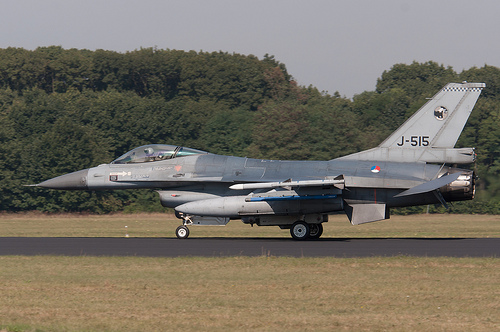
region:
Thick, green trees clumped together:
[0, 48, 498, 213]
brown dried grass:
[3, 212, 498, 329]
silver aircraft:
[22, 79, 484, 236]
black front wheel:
[176, 224, 189, 237]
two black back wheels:
[292, 223, 324, 239]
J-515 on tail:
[396, 134, 431, 149]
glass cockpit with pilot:
[111, 144, 198, 164]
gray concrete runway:
[0, 235, 498, 255]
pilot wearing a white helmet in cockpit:
[140, 145, 152, 157]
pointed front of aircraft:
[22, 167, 89, 189]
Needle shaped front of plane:
[24, 182, 36, 186]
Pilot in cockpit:
[145, 146, 154, 156]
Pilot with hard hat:
[143, 146, 154, 156]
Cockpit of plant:
[131, 150, 165, 158]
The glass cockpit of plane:
[130, 152, 165, 155]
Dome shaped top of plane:
[143, 143, 161, 146]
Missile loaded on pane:
[236, 181, 326, 186]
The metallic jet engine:
[466, 175, 471, 193]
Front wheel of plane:
[176, 225, 187, 236]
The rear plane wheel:
[293, 223, 306, 235]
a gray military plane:
[29, 78, 499, 265]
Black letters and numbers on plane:
[393, 131, 438, 153]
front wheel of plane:
[167, 220, 193, 239]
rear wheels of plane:
[283, 223, 335, 246]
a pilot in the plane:
[138, 144, 166, 166]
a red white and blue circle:
[369, 162, 387, 178]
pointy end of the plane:
[26, 159, 95, 203]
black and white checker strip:
[446, 78, 491, 93]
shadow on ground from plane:
[172, 228, 469, 250]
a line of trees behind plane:
[8, 37, 498, 221]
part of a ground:
[376, 258, 410, 298]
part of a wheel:
[295, 225, 311, 239]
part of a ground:
[363, 263, 400, 320]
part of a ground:
[347, 245, 398, 307]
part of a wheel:
[291, 215, 311, 240]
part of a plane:
[429, 110, 466, 182]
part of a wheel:
[290, 218, 313, 265]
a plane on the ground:
[11, 69, 498, 256]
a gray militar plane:
[31, 67, 493, 269]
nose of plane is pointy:
[18, 157, 97, 204]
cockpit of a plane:
[85, 133, 212, 173]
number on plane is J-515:
[380, 114, 452, 151]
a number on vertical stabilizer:
[375, 75, 489, 152]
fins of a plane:
[382, 145, 469, 209]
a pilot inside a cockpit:
[108, 133, 206, 169]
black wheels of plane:
[277, 215, 329, 248]